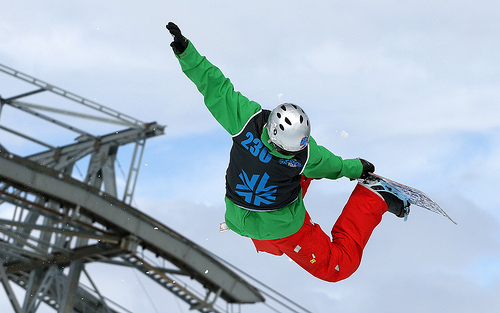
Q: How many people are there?
A: 1.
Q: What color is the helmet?
A: Silver.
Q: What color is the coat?
A: Green.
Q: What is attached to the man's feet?
A: Snowboard.